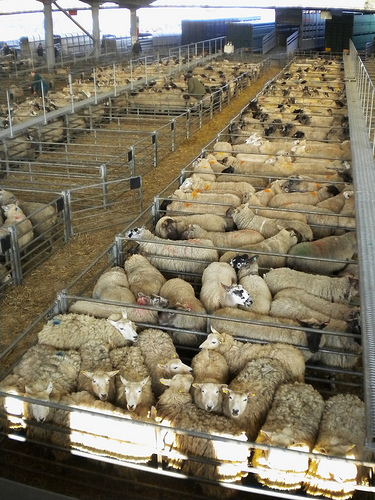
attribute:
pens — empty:
[31, 90, 191, 210]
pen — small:
[99, 251, 362, 341]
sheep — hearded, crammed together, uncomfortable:
[117, 229, 306, 322]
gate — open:
[60, 183, 148, 252]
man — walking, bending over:
[28, 69, 56, 101]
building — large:
[23, 12, 374, 253]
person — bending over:
[31, 67, 52, 90]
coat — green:
[39, 81, 50, 94]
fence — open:
[65, 184, 157, 229]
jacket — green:
[40, 84, 52, 93]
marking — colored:
[185, 186, 200, 201]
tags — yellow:
[192, 192, 202, 202]